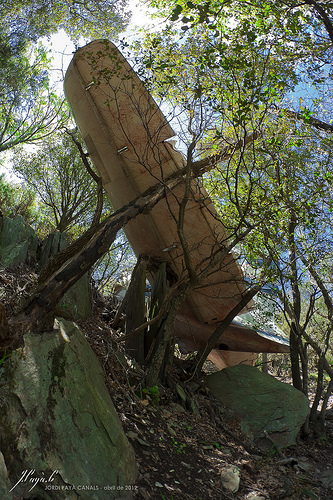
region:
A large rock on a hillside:
[199, 357, 315, 457]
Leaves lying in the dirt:
[129, 397, 209, 485]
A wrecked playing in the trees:
[74, 120, 283, 340]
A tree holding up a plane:
[54, 124, 268, 274]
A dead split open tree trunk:
[121, 247, 184, 375]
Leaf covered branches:
[204, 79, 278, 182]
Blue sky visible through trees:
[286, 71, 321, 102]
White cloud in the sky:
[6, 7, 123, 160]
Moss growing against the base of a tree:
[142, 381, 166, 406]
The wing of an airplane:
[57, 77, 265, 285]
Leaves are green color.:
[200, 70, 318, 221]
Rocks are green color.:
[24, 354, 122, 458]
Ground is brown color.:
[134, 391, 251, 485]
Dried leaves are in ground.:
[114, 340, 235, 498]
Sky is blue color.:
[239, 102, 332, 209]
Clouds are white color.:
[31, 9, 176, 52]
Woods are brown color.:
[68, 232, 117, 285]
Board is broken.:
[67, 69, 289, 369]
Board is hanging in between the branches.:
[68, 65, 249, 345]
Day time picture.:
[22, 29, 322, 424]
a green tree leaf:
[237, 97, 252, 109]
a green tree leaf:
[222, 105, 226, 115]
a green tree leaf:
[316, 179, 320, 193]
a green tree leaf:
[303, 223, 314, 229]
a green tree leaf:
[27, 186, 33, 192]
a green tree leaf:
[29, 175, 32, 179]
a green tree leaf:
[17, 206, 24, 211]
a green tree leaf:
[83, 198, 89, 203]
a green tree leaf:
[261, 288, 267, 291]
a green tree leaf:
[251, 320, 259, 330]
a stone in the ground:
[207, 361, 305, 447]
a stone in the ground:
[217, 459, 244, 498]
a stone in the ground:
[245, 487, 263, 497]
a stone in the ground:
[292, 452, 313, 472]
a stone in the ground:
[12, 315, 135, 497]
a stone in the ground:
[157, 399, 179, 426]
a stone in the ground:
[176, 381, 191, 408]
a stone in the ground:
[123, 419, 149, 452]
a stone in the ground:
[122, 370, 142, 399]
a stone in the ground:
[121, 345, 145, 374]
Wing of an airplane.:
[62, 35, 257, 324]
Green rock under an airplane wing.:
[200, 363, 311, 451]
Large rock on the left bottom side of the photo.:
[3, 315, 140, 498]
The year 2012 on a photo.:
[124, 484, 138, 492]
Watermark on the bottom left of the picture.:
[10, 467, 138, 493]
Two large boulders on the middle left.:
[2, 211, 93, 321]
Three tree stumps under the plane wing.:
[112, 250, 191, 393]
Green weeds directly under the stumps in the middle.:
[141, 385, 160, 409]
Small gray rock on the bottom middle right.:
[220, 460, 241, 494]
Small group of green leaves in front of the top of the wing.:
[76, 36, 136, 92]